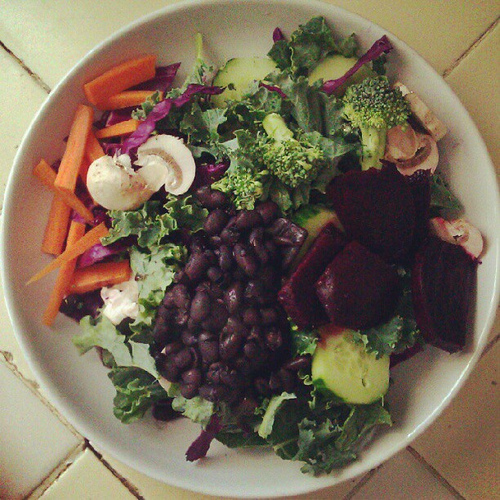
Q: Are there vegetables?
A: Yes, there are vegetables.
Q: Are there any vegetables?
A: Yes, there are vegetables.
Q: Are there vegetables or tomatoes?
A: Yes, there are vegetables.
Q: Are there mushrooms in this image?
A: Yes, there are mushrooms.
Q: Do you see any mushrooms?
A: Yes, there are mushrooms.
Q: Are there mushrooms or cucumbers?
A: Yes, there are mushrooms.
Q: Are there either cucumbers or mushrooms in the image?
A: Yes, there are mushrooms.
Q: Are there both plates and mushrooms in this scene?
A: Yes, there are both mushrooms and a plate.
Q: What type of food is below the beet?
A: The food is mushrooms.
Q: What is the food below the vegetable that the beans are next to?
A: The food is mushrooms.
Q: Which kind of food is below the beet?
A: The food is mushrooms.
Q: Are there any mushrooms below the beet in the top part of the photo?
A: Yes, there are mushrooms below the beet.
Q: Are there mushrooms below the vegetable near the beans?
A: Yes, there are mushrooms below the beet.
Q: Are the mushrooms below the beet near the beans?
A: Yes, the mushrooms are below the beet.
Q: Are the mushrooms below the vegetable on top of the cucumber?
A: Yes, the mushrooms are below the beet.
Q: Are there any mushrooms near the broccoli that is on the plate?
A: Yes, there are mushrooms near the broccoli.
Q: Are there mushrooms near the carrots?
A: Yes, there are mushrooms near the carrots.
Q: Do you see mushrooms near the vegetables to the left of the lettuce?
A: Yes, there are mushrooms near the carrots.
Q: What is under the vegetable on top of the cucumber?
A: The mushrooms are under the beet.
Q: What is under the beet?
A: The mushrooms are under the beet.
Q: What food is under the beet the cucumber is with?
A: The food is mushrooms.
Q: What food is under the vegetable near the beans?
A: The food is mushrooms.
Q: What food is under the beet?
A: The food is mushrooms.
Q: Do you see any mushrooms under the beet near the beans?
A: Yes, there are mushrooms under the beet.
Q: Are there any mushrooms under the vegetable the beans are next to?
A: Yes, there are mushrooms under the beet.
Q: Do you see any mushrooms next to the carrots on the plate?
A: Yes, there are mushrooms next to the carrots.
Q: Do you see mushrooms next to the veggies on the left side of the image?
A: Yes, there are mushrooms next to the carrots.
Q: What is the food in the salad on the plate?
A: The food is mushrooms.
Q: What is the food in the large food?
A: The food is mushrooms.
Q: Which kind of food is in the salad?
A: The food is mushrooms.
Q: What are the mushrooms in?
A: The mushrooms are in the salad.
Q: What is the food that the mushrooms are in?
A: The food is salad.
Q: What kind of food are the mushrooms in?
A: The mushrooms are in the salad.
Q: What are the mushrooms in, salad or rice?
A: The mushrooms are in salad.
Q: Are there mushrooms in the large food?
A: Yes, there are mushrooms in the salad.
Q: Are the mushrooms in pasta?
A: No, the mushrooms are in the salad.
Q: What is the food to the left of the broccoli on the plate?
A: The food is mushrooms.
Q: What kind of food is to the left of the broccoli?
A: The food is mushrooms.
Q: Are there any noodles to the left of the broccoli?
A: No, there are mushrooms to the left of the broccoli.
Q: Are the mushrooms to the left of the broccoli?
A: Yes, the mushrooms are to the left of the broccoli.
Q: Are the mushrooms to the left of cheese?
A: No, the mushrooms are to the left of the broccoli.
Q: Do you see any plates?
A: Yes, there is a plate.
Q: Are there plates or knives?
A: Yes, there is a plate.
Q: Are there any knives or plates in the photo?
A: Yes, there is a plate.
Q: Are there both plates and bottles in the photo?
A: No, there is a plate but no bottles.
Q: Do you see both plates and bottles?
A: No, there is a plate but no bottles.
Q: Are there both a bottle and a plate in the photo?
A: No, there is a plate but no bottles.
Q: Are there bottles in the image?
A: No, there are no bottles.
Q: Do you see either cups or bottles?
A: No, there are no bottles or cups.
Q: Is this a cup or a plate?
A: This is a plate.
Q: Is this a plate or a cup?
A: This is a plate.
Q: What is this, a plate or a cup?
A: This is a plate.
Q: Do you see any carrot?
A: Yes, there are carrots.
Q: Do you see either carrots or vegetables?
A: Yes, there are carrots.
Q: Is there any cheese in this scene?
A: No, there is no cheese.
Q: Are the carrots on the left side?
A: Yes, the carrots are on the left of the image.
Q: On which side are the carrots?
A: The carrots are on the left of the image.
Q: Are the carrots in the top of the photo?
A: Yes, the carrots are in the top of the image.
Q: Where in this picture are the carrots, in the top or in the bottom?
A: The carrots are in the top of the image.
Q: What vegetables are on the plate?
A: The vegetables are carrots.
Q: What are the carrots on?
A: The carrots are on the plate.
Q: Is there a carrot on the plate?
A: Yes, there are carrots on the plate.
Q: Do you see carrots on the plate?
A: Yes, there are carrots on the plate.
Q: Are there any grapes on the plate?
A: No, there are carrots on the plate.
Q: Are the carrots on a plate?
A: Yes, the carrots are on a plate.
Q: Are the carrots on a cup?
A: No, the carrots are on a plate.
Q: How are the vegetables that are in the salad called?
A: The vegetables are carrots.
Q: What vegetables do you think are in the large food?
A: The vegetables are carrots.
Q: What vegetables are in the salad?
A: The vegetables are carrots.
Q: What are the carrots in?
A: The carrots are in the salad.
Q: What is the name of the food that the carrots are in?
A: The food is salad.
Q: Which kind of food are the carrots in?
A: The carrots are in the salad.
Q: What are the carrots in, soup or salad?
A: The carrots are in salad.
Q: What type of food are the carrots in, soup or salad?
A: The carrots are in salad.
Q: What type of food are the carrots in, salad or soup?
A: The carrots are in salad.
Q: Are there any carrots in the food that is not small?
A: Yes, there are carrots in the salad.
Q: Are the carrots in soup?
A: No, the carrots are in the salad.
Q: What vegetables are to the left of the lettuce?
A: The vegetables are carrots.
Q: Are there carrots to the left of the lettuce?
A: Yes, there are carrots to the left of the lettuce.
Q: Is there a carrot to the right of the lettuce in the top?
A: No, the carrots are to the left of the lettuce.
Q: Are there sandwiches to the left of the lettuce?
A: No, there are carrots to the left of the lettuce.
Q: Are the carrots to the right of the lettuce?
A: No, the carrots are to the left of the lettuce.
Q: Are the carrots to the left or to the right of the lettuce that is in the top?
A: The carrots are to the left of the lettuce.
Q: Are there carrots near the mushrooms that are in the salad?
A: Yes, there are carrots near the mushrooms.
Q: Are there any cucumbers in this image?
A: Yes, there is a cucumber.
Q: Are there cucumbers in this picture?
A: Yes, there is a cucumber.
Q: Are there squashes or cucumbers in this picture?
A: Yes, there is a cucumber.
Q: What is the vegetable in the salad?
A: The vegetable is a cucumber.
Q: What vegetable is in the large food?
A: The vegetable is a cucumber.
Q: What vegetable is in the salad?
A: The vegetable is a cucumber.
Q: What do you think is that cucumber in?
A: The cucumber is in the salad.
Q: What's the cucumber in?
A: The cucumber is in the salad.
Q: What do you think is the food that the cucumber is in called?
A: The food is salad.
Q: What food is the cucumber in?
A: The cucumber is in the salad.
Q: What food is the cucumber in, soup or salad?
A: The cucumber is in salad.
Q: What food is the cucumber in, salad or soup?
A: The cucumber is in salad.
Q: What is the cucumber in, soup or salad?
A: The cucumber is in salad.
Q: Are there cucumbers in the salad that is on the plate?
A: Yes, there is a cucumber in the salad.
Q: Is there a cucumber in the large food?
A: Yes, there is a cucumber in the salad.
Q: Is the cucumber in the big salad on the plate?
A: Yes, the cucumber is in the salad.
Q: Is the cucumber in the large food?
A: Yes, the cucumber is in the salad.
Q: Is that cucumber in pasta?
A: No, the cucumber is in the salad.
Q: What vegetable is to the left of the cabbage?
A: The vegetable is a cucumber.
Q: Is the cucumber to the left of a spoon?
A: No, the cucumber is to the left of the cabbage.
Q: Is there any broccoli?
A: Yes, there is broccoli.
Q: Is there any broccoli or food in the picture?
A: Yes, there is broccoli.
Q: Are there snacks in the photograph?
A: No, there are no snacks.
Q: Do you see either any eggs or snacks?
A: No, there are no snacks or eggs.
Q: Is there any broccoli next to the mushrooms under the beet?
A: Yes, there is broccoli next to the mushrooms.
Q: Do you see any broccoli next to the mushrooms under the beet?
A: Yes, there is broccoli next to the mushrooms.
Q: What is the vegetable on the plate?
A: The vegetable is broccoli.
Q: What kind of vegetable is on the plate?
A: The vegetable is broccoli.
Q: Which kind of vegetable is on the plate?
A: The vegetable is broccoli.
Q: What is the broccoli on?
A: The broccoli is on the plate.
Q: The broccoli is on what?
A: The broccoli is on the plate.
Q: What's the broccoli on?
A: The broccoli is on the plate.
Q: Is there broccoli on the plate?
A: Yes, there is broccoli on the plate.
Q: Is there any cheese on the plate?
A: No, there is broccoli on the plate.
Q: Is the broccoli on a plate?
A: Yes, the broccoli is on a plate.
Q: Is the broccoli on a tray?
A: No, the broccoli is on a plate.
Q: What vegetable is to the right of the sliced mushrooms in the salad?
A: The vegetable is broccoli.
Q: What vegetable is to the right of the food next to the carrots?
A: The vegetable is broccoli.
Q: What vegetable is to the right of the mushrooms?
A: The vegetable is broccoli.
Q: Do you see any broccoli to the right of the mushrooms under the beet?
A: Yes, there is broccoli to the right of the mushrooms.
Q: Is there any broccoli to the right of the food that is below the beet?
A: Yes, there is broccoli to the right of the mushrooms.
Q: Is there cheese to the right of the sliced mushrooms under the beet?
A: No, there is broccoli to the right of the mushrooms.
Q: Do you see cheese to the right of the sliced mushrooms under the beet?
A: No, there is broccoli to the right of the mushrooms.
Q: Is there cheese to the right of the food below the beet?
A: No, there is broccoli to the right of the mushrooms.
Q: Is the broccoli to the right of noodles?
A: No, the broccoli is to the right of the mushrooms.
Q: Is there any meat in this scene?
A: No, there is no meat.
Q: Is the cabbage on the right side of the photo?
A: Yes, the cabbage is on the right of the image.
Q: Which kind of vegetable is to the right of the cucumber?
A: The vegetable is a cabbage.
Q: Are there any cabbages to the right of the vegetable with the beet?
A: Yes, there is a cabbage to the right of the cucumber.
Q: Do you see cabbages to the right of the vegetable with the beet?
A: Yes, there is a cabbage to the right of the cucumber.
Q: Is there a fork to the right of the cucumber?
A: No, there is a cabbage to the right of the cucumber.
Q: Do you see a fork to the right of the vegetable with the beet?
A: No, there is a cabbage to the right of the cucumber.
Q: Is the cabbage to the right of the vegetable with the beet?
A: Yes, the cabbage is to the right of the cucumber.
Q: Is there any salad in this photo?
A: Yes, there is salad.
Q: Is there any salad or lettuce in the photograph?
A: Yes, there is salad.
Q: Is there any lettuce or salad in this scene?
A: Yes, there is salad.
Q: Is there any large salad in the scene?
A: Yes, there is large salad.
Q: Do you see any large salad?
A: Yes, there is large salad.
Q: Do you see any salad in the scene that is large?
A: Yes, there is salad that is large.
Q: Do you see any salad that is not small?
A: Yes, there is large salad.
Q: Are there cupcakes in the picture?
A: No, there are no cupcakes.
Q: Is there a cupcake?
A: No, there are no cupcakes.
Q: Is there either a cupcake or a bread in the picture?
A: No, there are no cupcakes or breads.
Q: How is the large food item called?
A: The food item is salad.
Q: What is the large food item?
A: The food item is salad.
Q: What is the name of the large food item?
A: The food item is salad.